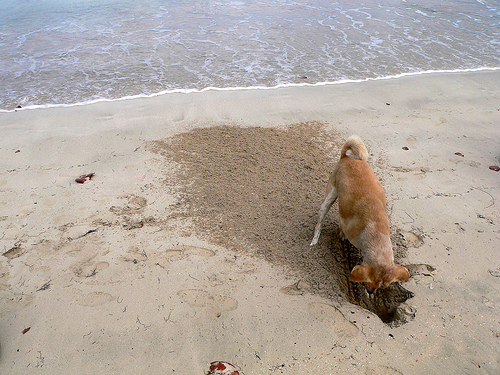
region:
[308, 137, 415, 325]
A dog is digging a hole in the ground.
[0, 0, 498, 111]
The water is foamy.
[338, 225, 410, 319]
The digging dog is uncovering something.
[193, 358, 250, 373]
Something red is in the sand.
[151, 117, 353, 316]
The loose sand is darker than the other sand.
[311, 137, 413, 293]
The dog is brown and white.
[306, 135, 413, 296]
The dog is looking down.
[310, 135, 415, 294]
The dog has two ears.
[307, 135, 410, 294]
The dog is a small breed.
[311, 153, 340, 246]
The leg is mostly white.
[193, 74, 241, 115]
edge of a shhore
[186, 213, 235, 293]
part of a beach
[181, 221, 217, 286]
part of a beach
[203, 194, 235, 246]
part of a beach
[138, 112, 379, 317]
the sand is stirred up where the dog dug a hole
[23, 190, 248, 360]
the prints are in the sand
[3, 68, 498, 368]
the dog is on the beach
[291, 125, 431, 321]
this is a dog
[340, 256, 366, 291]
this is the dog's ear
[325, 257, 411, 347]
the dog is digging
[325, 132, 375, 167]
this is the dog's tail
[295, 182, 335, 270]
this is the dog's leg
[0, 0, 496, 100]
this is the ocean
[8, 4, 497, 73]
the foam is on the water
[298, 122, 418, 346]
orange dog digging hole in the sand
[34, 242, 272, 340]
footprints and small twigs in the sand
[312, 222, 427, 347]
deep hole dug by furry dog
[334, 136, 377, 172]
hair on tail of dog is longer than other fur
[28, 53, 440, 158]
ocean water washing up on the sand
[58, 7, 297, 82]
bubbles and foam in moving ocean water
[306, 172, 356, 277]
white fur on dog leg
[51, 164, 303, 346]
fresh dirt dug up by the dog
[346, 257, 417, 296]
dog's brown folded furry ears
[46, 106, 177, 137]
smooth white sand that water has touched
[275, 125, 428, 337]
dog digging hole in sand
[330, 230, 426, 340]
hole in sand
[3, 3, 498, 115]
edge of body of water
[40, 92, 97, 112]
white froth on top of water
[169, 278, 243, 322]
footprint in sand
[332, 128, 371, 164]
tan dog tail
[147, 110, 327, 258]
pile of sand on beach behind the dog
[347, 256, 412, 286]
two dog ears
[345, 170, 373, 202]
brown dog fur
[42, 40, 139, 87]
ripples in body of water